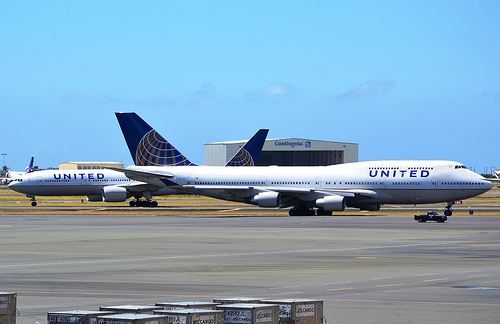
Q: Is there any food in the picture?
A: Yes, there is food.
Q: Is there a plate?
A: No, there are no plates.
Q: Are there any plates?
A: No, there are no plates.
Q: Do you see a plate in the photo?
A: No, there are no plates.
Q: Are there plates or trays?
A: No, there are no plates or trays.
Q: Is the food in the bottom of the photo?
A: Yes, the food is in the bottom of the image.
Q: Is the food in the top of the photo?
A: No, the food is in the bottom of the image.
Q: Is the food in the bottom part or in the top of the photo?
A: The food is in the bottom of the image.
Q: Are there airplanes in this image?
A: Yes, there is an airplane.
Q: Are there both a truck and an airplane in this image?
A: Yes, there are both an airplane and a truck.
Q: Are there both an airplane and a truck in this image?
A: Yes, there are both an airplane and a truck.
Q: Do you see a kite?
A: No, there are no kites.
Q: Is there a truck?
A: Yes, there is a truck.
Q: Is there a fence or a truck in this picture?
A: Yes, there is a truck.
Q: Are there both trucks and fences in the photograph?
A: No, there is a truck but no fences.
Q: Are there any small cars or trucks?
A: Yes, there is a small truck.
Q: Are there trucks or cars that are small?
A: Yes, the truck is small.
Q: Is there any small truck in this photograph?
A: Yes, there is a small truck.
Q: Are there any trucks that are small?
A: Yes, there is a truck that is small.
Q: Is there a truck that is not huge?
A: Yes, there is a small truck.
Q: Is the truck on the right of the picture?
A: Yes, the truck is on the right of the image.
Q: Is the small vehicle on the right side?
A: Yes, the truck is on the right of the image.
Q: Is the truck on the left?
A: No, the truck is on the right of the image.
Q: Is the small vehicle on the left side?
A: No, the truck is on the right of the image.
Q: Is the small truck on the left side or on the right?
A: The truck is on the right of the image.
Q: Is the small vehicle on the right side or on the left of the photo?
A: The truck is on the right of the image.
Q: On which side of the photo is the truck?
A: The truck is on the right of the image.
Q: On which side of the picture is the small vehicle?
A: The truck is on the right of the image.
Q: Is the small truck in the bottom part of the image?
A: Yes, the truck is in the bottom of the image.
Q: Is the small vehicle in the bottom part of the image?
A: Yes, the truck is in the bottom of the image.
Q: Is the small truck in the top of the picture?
A: No, the truck is in the bottom of the image.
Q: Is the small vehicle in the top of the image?
A: No, the truck is in the bottom of the image.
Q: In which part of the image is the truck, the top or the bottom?
A: The truck is in the bottom of the image.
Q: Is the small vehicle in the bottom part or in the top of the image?
A: The truck is in the bottom of the image.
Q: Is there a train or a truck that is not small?
A: No, there is a truck but it is small.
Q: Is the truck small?
A: Yes, the truck is small.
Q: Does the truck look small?
A: Yes, the truck is small.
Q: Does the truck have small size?
A: Yes, the truck is small.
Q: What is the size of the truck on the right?
A: The truck is small.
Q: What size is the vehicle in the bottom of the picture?
A: The truck is small.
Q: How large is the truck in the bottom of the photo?
A: The truck is small.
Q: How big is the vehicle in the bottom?
A: The truck is small.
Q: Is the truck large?
A: No, the truck is small.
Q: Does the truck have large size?
A: No, the truck is small.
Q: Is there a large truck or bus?
A: No, there is a truck but it is small.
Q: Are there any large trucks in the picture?
A: No, there is a truck but it is small.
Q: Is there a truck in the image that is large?
A: No, there is a truck but it is small.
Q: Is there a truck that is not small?
A: No, there is a truck but it is small.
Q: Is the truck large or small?
A: The truck is small.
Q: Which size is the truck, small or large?
A: The truck is small.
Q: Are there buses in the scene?
A: No, there are no buses.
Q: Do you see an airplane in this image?
A: Yes, there is an airplane.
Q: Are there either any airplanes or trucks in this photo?
A: Yes, there is an airplane.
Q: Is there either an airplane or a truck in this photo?
A: Yes, there is an airplane.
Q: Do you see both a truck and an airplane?
A: Yes, there are both an airplane and a truck.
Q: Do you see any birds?
A: No, there are no birds.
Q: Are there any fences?
A: No, there are no fences.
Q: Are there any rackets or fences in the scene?
A: No, there are no fences or rackets.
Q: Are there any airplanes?
A: Yes, there is an airplane.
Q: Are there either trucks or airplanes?
A: Yes, there is an airplane.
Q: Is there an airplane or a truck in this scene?
A: Yes, there is an airplane.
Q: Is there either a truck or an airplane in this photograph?
A: Yes, there is an airplane.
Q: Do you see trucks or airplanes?
A: Yes, there is an airplane.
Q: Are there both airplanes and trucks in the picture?
A: Yes, there are both an airplane and a truck.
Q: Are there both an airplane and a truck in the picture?
A: Yes, there are both an airplane and a truck.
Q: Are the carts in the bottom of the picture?
A: Yes, the carts are in the bottom of the image.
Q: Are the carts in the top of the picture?
A: No, the carts are in the bottom of the image.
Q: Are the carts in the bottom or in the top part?
A: The carts are in the bottom of the image.